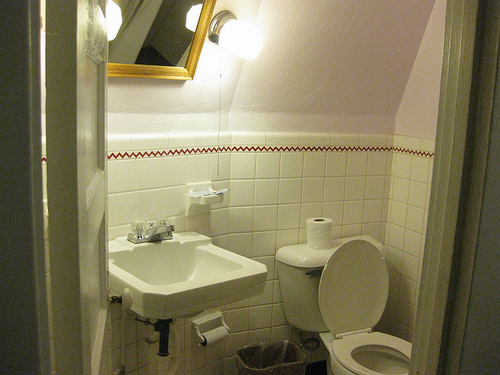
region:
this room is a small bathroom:
[115, 5, 419, 366]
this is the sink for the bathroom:
[111, 223, 280, 303]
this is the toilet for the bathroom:
[287, 214, 403, 374]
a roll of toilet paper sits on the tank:
[287, 205, 339, 252]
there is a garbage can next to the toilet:
[236, 332, 309, 372]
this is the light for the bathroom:
[206, 15, 272, 67]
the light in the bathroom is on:
[208, 21, 274, 66]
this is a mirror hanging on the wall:
[110, 3, 197, 83]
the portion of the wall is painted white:
[278, 35, 421, 122]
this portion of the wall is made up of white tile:
[229, 174, 399, 216]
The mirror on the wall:
[101, 0, 216, 85]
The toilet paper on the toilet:
[303, 206, 336, 259]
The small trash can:
[232, 332, 312, 374]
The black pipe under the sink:
[147, 315, 179, 361]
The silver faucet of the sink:
[126, 215, 178, 246]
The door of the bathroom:
[45, 2, 118, 374]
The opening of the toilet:
[348, 336, 408, 373]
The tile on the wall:
[35, 127, 438, 369]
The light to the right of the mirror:
[207, 9, 269, 68]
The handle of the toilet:
[302, 263, 323, 285]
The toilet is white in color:
[273, 200, 413, 372]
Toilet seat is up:
[310, 227, 417, 373]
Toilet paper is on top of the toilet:
[290, 205, 343, 257]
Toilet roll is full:
[298, 210, 342, 254]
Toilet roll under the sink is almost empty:
[186, 315, 241, 357]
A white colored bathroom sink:
[107, 206, 275, 338]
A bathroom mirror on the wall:
[106, 2, 213, 85]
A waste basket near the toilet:
[229, 335, 309, 374]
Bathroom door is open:
[28, 2, 148, 374]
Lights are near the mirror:
[106, 2, 271, 71]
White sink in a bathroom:
[105, 220, 267, 313]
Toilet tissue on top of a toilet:
[305, 218, 333, 250]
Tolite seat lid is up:
[315, 238, 390, 335]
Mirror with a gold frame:
[105, 8, 210, 78]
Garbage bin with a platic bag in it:
[234, 341, 309, 373]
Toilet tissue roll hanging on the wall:
[192, 311, 230, 346]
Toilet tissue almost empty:
[193, 312, 235, 347]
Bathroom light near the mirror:
[210, 10, 262, 62]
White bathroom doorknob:
[107, 288, 133, 311]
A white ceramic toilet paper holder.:
[193, 312, 230, 348]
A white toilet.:
[276, 229, 415, 374]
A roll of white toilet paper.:
[306, 214, 333, 250]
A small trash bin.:
[234, 336, 306, 372]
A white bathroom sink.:
[104, 227, 268, 312]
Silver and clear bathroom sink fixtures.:
[126, 217, 179, 240]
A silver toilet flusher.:
[302, 267, 321, 282]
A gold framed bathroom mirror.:
[104, 2, 217, 85]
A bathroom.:
[28, 4, 497, 374]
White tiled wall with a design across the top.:
[38, 136, 440, 373]